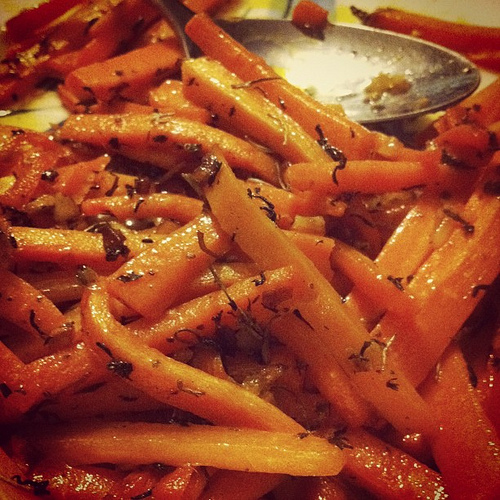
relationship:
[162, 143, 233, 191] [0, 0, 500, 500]
herbs cover carrots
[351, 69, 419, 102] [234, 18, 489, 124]
carrots on spoon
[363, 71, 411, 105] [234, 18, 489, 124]
carrots on spoon